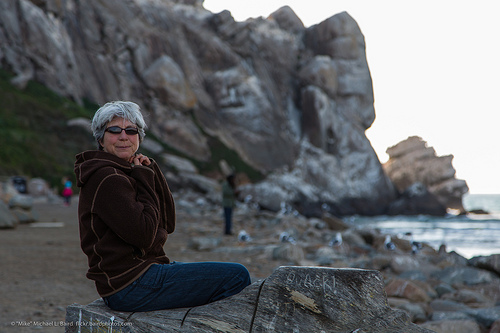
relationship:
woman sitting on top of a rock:
[71, 100, 254, 311] [65, 263, 420, 330]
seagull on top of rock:
[382, 234, 396, 251] [377, 248, 403, 264]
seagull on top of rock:
[409, 237, 425, 258] [409, 253, 431, 271]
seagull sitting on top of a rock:
[327, 227, 347, 248] [322, 246, 354, 265]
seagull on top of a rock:
[276, 229, 296, 246] [268, 244, 306, 265]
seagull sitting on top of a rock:
[234, 228, 254, 243] [241, 239, 253, 245]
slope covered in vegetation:
[1, 59, 73, 201] [2, 90, 56, 173]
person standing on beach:
[218, 171, 248, 235] [1, 172, 498, 331]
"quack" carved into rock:
[283, 270, 340, 299] [65, 263, 420, 330]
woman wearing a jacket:
[71, 100, 254, 311] [72, 148, 177, 297]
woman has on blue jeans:
[71, 100, 254, 311] [102, 261, 253, 313]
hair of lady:
[90, 100, 150, 147] [71, 100, 254, 311]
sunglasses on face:
[101, 123, 141, 136] [100, 115, 142, 158]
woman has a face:
[71, 100, 254, 311] [100, 115, 142, 158]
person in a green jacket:
[218, 171, 248, 235] [220, 183, 237, 209]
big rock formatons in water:
[301, 10, 468, 218] [339, 208, 499, 256]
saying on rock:
[283, 270, 340, 299] [65, 263, 420, 330]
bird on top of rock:
[276, 229, 296, 246] [268, 244, 306, 265]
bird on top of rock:
[327, 227, 347, 248] [322, 246, 354, 265]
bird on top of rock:
[383, 232, 400, 253] [377, 248, 403, 264]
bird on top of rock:
[409, 237, 425, 258] [409, 253, 431, 271]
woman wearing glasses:
[71, 100, 254, 311] [101, 123, 141, 136]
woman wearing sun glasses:
[71, 100, 254, 311] [101, 123, 141, 136]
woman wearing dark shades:
[71, 100, 254, 311] [101, 123, 141, 136]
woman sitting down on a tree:
[71, 100, 254, 311] [65, 263, 420, 330]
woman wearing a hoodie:
[71, 100, 254, 311] [72, 148, 177, 297]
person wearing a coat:
[218, 171, 248, 235] [220, 183, 237, 209]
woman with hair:
[71, 100, 254, 311] [90, 100, 150, 147]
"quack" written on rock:
[283, 270, 340, 299] [65, 263, 420, 330]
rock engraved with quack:
[65, 263, 420, 330] [283, 270, 340, 299]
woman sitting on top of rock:
[71, 100, 254, 311] [65, 263, 420, 330]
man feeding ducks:
[218, 171, 248, 235] [236, 225, 422, 260]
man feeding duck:
[218, 171, 248, 235] [382, 234, 396, 251]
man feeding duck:
[218, 171, 248, 235] [409, 237, 425, 258]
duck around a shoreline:
[409, 237, 425, 258] [312, 207, 499, 306]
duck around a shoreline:
[383, 232, 400, 253] [312, 207, 499, 306]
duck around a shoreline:
[327, 227, 347, 248] [312, 207, 499, 306]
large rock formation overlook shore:
[298, 11, 394, 219] [339, 214, 500, 260]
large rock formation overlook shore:
[384, 135, 472, 219] [339, 214, 500, 260]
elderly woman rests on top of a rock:
[71, 100, 254, 311] [65, 263, 420, 330]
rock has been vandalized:
[65, 263, 420, 330] [283, 269, 373, 332]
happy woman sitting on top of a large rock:
[71, 100, 254, 311] [65, 263, 420, 330]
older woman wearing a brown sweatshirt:
[71, 100, 254, 311] [72, 148, 177, 297]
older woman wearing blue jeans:
[71, 100, 254, 311] [102, 261, 253, 313]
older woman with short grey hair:
[71, 100, 254, 311] [90, 100, 150, 147]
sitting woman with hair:
[71, 100, 254, 311] [90, 100, 150, 147]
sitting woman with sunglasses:
[71, 100, 254, 311] [101, 123, 141, 136]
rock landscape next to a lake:
[1, 0, 472, 217] [339, 208, 499, 256]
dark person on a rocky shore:
[218, 171, 248, 235] [244, 209, 341, 265]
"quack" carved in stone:
[285, 273, 332, 293] [65, 263, 420, 330]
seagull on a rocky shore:
[234, 228, 254, 243] [244, 209, 341, 265]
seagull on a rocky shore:
[276, 229, 296, 246] [244, 209, 341, 265]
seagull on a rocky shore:
[327, 227, 347, 248] [244, 209, 341, 265]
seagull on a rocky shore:
[382, 234, 396, 251] [355, 229, 499, 267]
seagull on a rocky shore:
[409, 237, 425, 258] [355, 229, 499, 267]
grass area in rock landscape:
[2, 90, 56, 173] [1, 1, 75, 208]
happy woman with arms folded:
[71, 100, 254, 311] [123, 153, 176, 249]